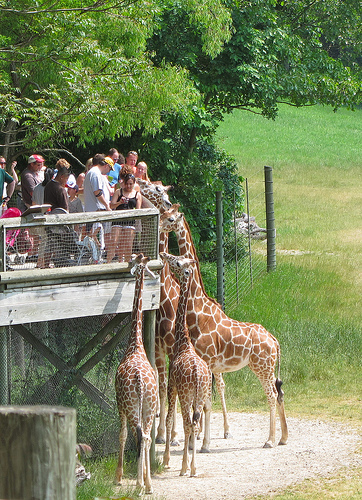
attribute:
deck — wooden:
[0, 209, 169, 461]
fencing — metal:
[0, 212, 156, 280]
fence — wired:
[221, 172, 269, 303]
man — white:
[19, 154, 41, 261]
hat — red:
[25, 153, 45, 163]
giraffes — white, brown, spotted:
[112, 174, 287, 494]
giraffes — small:
[56, 191, 349, 454]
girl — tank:
[37, 159, 84, 269]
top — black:
[108, 185, 146, 220]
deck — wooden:
[0, 204, 167, 325]